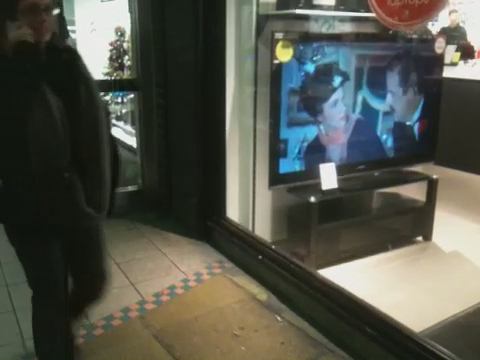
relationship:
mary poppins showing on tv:
[297, 62, 391, 161] [268, 30, 437, 179]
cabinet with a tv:
[292, 167, 443, 271] [268, 30, 437, 179]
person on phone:
[2, 1, 138, 360] [6, 9, 39, 54]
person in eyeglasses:
[2, 1, 138, 360] [7, 4, 62, 17]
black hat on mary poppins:
[306, 45, 344, 96] [297, 62, 391, 161]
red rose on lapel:
[419, 121, 429, 131] [381, 52, 430, 160]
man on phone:
[2, 1, 138, 360] [6, 9, 39, 54]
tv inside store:
[268, 30, 437, 179] [442, 2, 476, 299]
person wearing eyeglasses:
[2, 1, 138, 360] [15, 4, 63, 20]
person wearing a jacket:
[2, 1, 138, 360] [2, 45, 116, 228]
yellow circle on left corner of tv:
[271, 39, 295, 69] [268, 30, 437, 179]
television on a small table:
[268, 30, 437, 179] [292, 167, 443, 271]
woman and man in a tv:
[298, 45, 433, 158] [268, 30, 437, 179]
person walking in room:
[2, 1, 138, 360] [10, 3, 473, 353]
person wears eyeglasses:
[2, 1, 138, 360] [7, 4, 62, 17]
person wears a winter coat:
[2, 1, 138, 360] [2, 45, 116, 228]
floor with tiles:
[424, 249, 480, 302] [443, 186, 472, 219]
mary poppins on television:
[297, 62, 391, 161] [268, 30, 437, 179]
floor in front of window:
[424, 249, 480, 302] [65, 6, 154, 183]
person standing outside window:
[99, 23, 132, 101] [65, 6, 154, 183]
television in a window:
[268, 30, 437, 179] [65, 6, 154, 183]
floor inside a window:
[140, 227, 212, 279] [65, 6, 154, 183]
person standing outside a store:
[2, 1, 138, 360] [442, 2, 476, 299]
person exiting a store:
[2, 1, 138, 360] [442, 2, 476, 299]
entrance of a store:
[118, 4, 222, 333] [442, 2, 476, 299]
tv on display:
[268, 30, 437, 179] [254, 16, 457, 285]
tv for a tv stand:
[268, 30, 437, 179] [292, 167, 443, 271]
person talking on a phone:
[2, 1, 138, 360] [6, 9, 39, 54]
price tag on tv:
[316, 155, 345, 193] [268, 30, 437, 179]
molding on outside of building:
[213, 211, 473, 360] [0, 1, 333, 360]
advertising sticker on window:
[366, 1, 452, 34] [356, 35, 456, 96]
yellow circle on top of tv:
[275, 39, 296, 64] [268, 30, 437, 179]